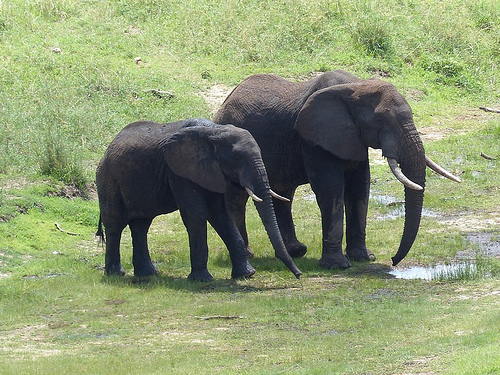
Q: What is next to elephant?
A: Elephant.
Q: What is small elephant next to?
A: Large elephant.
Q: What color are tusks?
A: White.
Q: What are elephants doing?
A: Walking.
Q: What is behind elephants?
A: Grassy hill.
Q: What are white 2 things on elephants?
A: Tusks.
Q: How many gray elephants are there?
A: 2.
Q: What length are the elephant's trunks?
A: Long.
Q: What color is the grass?
A: Green.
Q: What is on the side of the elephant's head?
A: Ears.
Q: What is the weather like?
A: Sunny.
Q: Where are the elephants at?
A: Field.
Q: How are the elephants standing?
A: Side by side.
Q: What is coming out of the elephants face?
A: Tusks.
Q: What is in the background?
A: Weeds.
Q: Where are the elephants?
A: On the grass.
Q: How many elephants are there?
A: 2.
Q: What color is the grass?
A: Green.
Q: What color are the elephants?
A: Gray.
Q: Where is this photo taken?
A: In the wild.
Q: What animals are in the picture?
A: Elephants.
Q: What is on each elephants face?
A: Tusks.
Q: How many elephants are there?
A: Two.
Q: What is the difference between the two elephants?
A: Their size.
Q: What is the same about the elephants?
A: Their color.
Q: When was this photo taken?
A: During the day.